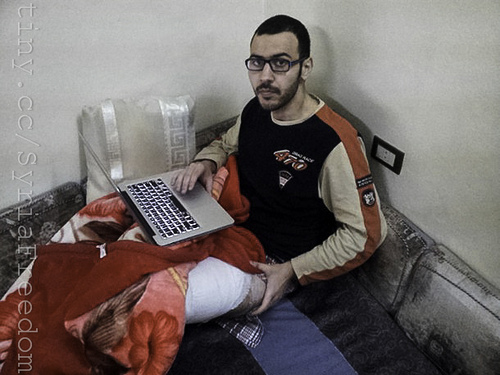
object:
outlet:
[373, 142, 398, 167]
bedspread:
[0, 272, 447, 373]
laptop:
[78, 131, 236, 248]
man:
[172, 15, 386, 322]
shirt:
[192, 93, 387, 286]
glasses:
[245, 54, 310, 74]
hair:
[248, 14, 311, 64]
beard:
[255, 75, 302, 111]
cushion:
[82, 93, 196, 203]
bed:
[2, 115, 497, 373]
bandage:
[183, 255, 253, 323]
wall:
[1, 1, 264, 210]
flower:
[126, 309, 184, 375]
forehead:
[249, 33, 298, 58]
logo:
[273, 147, 308, 173]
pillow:
[358, 194, 436, 312]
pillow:
[394, 243, 499, 373]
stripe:
[302, 103, 379, 294]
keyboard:
[125, 177, 197, 239]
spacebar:
[170, 196, 186, 214]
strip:
[101, 99, 123, 180]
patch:
[362, 188, 374, 206]